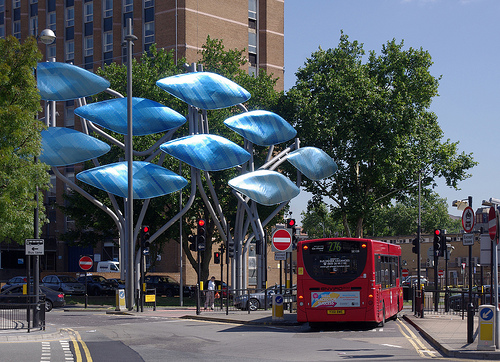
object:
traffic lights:
[134, 216, 454, 261]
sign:
[268, 227, 295, 252]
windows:
[65, 17, 222, 74]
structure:
[37, 45, 336, 236]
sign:
[73, 253, 97, 273]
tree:
[273, 23, 478, 237]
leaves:
[327, 61, 395, 126]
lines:
[59, 320, 92, 359]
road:
[73, 316, 408, 358]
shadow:
[178, 307, 345, 333]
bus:
[220, 206, 451, 330]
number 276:
[322, 237, 345, 253]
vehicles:
[42, 254, 267, 324]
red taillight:
[57, 294, 64, 298]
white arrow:
[474, 303, 498, 350]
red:
[430, 227, 445, 239]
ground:
[3, 278, 473, 359]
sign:
[435, 278, 497, 323]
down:
[466, 292, 498, 335]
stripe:
[273, 234, 291, 246]